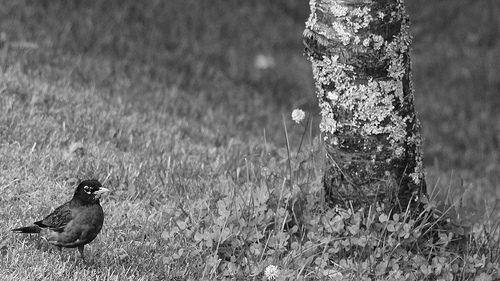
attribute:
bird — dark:
[9, 170, 142, 267]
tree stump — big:
[300, 0, 440, 240]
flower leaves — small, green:
[298, 197, 420, 275]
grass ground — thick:
[66, 98, 218, 220]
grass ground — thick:
[132, 40, 267, 190]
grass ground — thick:
[437, 99, 498, 268]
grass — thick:
[1, 1, 484, 278]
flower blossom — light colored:
[289, 107, 307, 124]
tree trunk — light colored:
[302, 0, 431, 218]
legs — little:
[54, 246, 99, 268]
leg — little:
[53, 247, 67, 264]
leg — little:
[75, 246, 99, 267]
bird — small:
[12, 175, 111, 257]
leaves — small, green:
[211, 161, 307, 280]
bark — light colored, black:
[300, 2, 431, 222]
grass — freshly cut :
[250, 214, 483, 264]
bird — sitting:
[26, 170, 104, 240]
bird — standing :
[32, 176, 115, 245]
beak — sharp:
[97, 180, 115, 200]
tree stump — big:
[299, 2, 435, 219]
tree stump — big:
[302, 0, 418, 184]